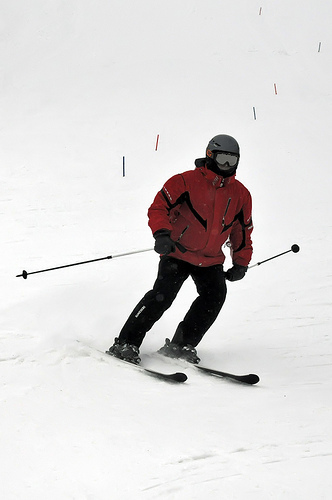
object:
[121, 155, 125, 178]
stick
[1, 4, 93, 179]
snow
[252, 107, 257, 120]
stick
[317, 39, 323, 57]
stick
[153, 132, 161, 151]
stick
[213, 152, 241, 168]
goggles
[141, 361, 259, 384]
ski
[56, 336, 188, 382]
ski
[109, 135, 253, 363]
skier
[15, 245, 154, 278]
pole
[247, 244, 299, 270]
pole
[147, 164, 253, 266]
coat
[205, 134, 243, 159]
helmet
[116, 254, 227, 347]
pants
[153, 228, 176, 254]
glove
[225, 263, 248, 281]
glove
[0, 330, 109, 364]
tracks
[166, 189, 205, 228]
stripe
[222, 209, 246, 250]
stripe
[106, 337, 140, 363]
boot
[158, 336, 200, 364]
boot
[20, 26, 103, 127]
part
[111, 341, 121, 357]
part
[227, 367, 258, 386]
part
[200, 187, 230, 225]
part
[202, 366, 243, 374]
edge